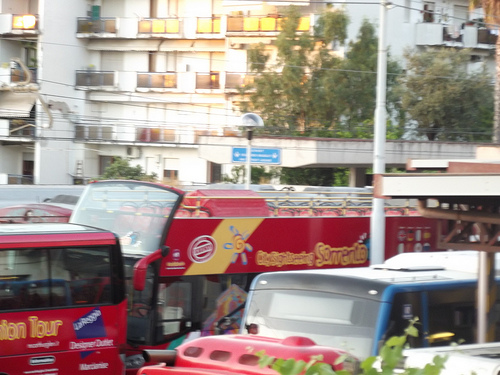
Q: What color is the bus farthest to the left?
A: Red.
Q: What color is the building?
A: White.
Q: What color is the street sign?
A: Blue.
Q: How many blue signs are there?
A: One.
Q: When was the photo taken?
A: Daytime.